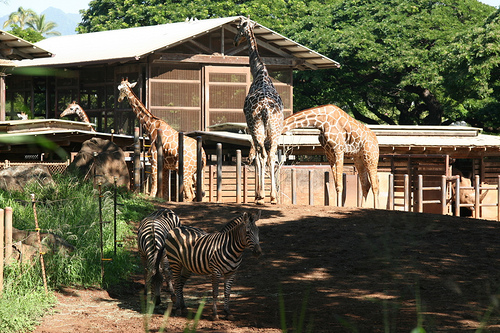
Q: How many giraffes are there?
A: 4.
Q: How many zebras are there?
A: 2.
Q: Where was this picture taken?
A: Zoo.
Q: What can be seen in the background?
A: Green trees.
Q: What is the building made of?
A: Wood.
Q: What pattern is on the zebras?
A: Black and white stripes.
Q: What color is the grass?
A: Green.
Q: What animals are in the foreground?
A: Zebras.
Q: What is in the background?
A: Trees.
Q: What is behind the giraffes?
A: A building.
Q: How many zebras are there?
A: 2.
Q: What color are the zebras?
A: Black and white.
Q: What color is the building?
A: Brown.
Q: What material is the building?
A: Wood.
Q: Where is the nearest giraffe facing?
A: Away from camera.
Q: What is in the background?
A: Trees.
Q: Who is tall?
A: Giraffe.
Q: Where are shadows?
A: On the ground.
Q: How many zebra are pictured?
A: Two.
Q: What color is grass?
A: Green.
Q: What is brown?
A: The dirt.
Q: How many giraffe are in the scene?
A: Four.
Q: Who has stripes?
A: Zebra.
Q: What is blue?
A: Sky.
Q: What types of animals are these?
A: Giraffes and zebras.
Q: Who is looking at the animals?
A: The photographer.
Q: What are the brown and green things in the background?
A: Trees.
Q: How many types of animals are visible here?
A: Two.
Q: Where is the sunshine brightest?
A: At the top of the slope, where the giraffes are.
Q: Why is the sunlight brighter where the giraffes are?
A: It is higher.